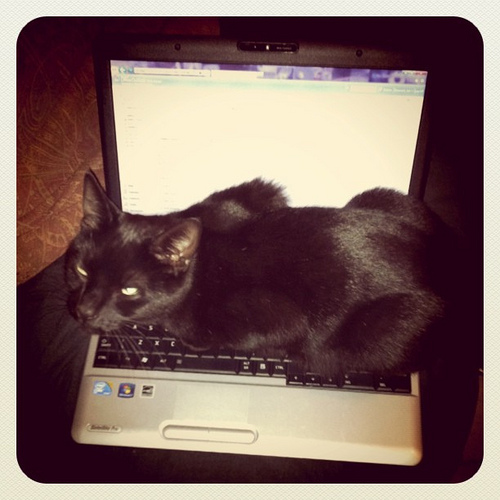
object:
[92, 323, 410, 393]
keyboard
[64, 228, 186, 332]
face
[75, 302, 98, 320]
nose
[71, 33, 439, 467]
computer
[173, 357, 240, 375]
bar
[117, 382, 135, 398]
logo sticker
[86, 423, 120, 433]
laptop sticker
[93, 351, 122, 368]
key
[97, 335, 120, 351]
key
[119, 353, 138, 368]
key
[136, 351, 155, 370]
key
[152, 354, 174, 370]
key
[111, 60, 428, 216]
web page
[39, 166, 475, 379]
cat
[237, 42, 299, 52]
webcam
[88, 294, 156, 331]
cheek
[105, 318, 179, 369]
whisker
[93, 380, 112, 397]
sticker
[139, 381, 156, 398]
sticker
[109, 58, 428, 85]
image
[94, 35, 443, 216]
screen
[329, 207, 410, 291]
light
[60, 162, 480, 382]
fur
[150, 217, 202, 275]
ear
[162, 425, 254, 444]
button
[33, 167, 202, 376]
head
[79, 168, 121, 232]
ear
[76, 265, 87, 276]
eye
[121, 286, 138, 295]
eye